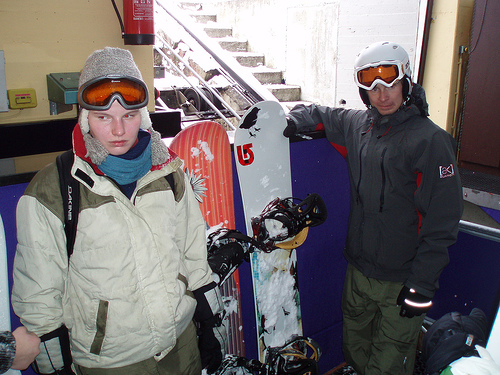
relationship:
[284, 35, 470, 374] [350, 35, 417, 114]
man wearing helmet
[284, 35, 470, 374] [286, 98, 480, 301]
snowboarder wearing jacket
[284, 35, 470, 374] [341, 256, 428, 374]
snowboarder wearing pants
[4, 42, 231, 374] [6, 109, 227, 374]
snowboarder wearing coat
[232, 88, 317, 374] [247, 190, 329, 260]
snowboard has binding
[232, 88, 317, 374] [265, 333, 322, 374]
snowboard has binding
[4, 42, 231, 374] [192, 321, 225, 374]
snowboarder wearing glove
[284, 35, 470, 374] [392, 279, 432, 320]
snowboarder wearing glove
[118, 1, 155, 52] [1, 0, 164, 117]
extinguisher on wall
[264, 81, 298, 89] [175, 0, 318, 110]
snow on stairs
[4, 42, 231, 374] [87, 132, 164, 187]
snowboarder wearing scarf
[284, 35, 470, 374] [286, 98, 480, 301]
snowboarder in jacket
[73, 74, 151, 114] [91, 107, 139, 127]
googles protect eyes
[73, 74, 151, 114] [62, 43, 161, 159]
googles on head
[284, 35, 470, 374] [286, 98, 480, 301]
ma wearing jacket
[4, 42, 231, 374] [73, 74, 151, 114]
snowboarder wearing goggles